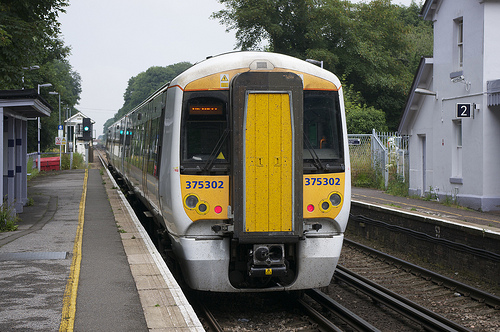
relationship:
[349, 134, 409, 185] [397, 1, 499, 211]
fence next to building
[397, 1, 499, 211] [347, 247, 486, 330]
building next to tracks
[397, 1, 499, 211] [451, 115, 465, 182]
building has window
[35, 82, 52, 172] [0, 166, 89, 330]
lamp post on platform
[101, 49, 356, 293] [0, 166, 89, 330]
train on platform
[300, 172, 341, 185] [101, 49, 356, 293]
numbers on train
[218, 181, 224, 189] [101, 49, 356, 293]
number on train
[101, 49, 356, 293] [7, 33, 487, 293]
train moving through city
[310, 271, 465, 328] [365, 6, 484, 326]
tracks on right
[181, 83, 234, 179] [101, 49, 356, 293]
window on train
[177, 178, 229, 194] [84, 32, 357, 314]
number painted on train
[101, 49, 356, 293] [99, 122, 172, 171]
train carrying passengers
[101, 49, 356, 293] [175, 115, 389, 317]
train approaching stop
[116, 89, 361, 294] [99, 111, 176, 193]
train picked up passengers